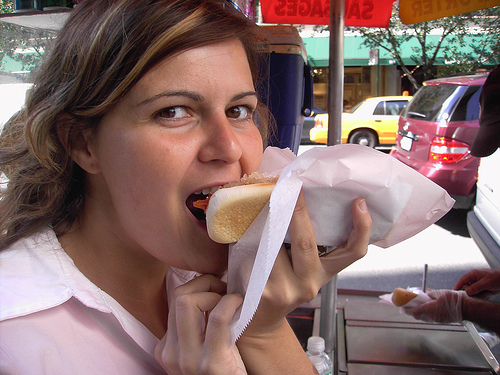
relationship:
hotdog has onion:
[196, 165, 407, 245] [220, 163, 294, 186]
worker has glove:
[397, 63, 498, 348] [409, 289, 466, 325]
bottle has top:
[299, 332, 338, 373] [306, 334, 326, 349]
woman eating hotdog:
[3, 6, 373, 371] [196, 165, 407, 245]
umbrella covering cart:
[227, 4, 498, 30] [283, 283, 495, 371]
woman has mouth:
[3, 6, 373, 371] [185, 177, 242, 247]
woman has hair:
[3, 6, 373, 371] [3, 5, 285, 255]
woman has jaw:
[3, 6, 373, 371] [133, 207, 257, 276]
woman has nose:
[3, 6, 373, 371] [195, 108, 244, 168]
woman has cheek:
[3, 6, 373, 371] [103, 132, 199, 193]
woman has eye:
[3, 6, 373, 371] [154, 99, 196, 129]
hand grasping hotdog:
[230, 184, 377, 317] [196, 165, 407, 245]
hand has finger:
[230, 184, 377, 317] [318, 198, 371, 276]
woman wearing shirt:
[3, 6, 373, 371] [1, 218, 223, 371]